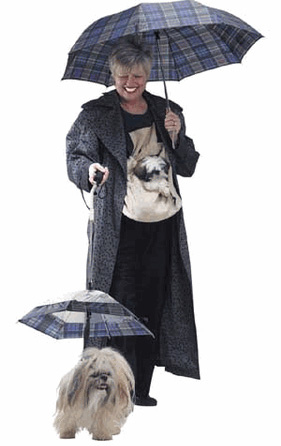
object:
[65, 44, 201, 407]
woman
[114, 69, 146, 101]
face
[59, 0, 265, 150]
umbrella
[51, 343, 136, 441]
dog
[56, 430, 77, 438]
foot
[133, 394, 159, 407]
shoe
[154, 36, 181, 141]
handle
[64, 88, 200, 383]
coat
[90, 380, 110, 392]
mouth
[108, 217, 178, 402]
trousers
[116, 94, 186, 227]
shirt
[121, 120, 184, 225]
drawing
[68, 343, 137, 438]
hair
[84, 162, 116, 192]
hand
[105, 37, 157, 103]
head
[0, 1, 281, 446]
background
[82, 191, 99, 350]
leash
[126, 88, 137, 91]
teeth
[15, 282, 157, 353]
umbrella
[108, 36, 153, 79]
hair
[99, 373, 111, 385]
nose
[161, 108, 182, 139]
hand